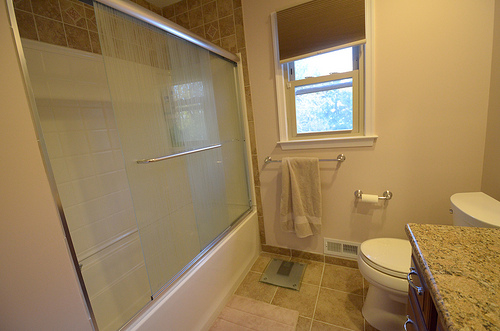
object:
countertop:
[405, 220, 499, 330]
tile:
[217, 14, 235, 39]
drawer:
[410, 256, 439, 331]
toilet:
[356, 191, 498, 330]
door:
[14, 0, 261, 324]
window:
[275, 48, 358, 141]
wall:
[20, 1, 494, 328]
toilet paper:
[360, 193, 377, 204]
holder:
[353, 189, 391, 202]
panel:
[260, 256, 308, 291]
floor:
[198, 252, 372, 330]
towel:
[279, 156, 323, 240]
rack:
[262, 156, 345, 165]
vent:
[323, 238, 359, 261]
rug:
[201, 293, 301, 330]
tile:
[247, 252, 292, 273]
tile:
[21, 48, 75, 76]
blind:
[276, 1, 367, 66]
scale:
[258, 257, 306, 291]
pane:
[293, 78, 353, 134]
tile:
[232, 253, 365, 330]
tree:
[293, 78, 353, 134]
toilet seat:
[359, 238, 413, 280]